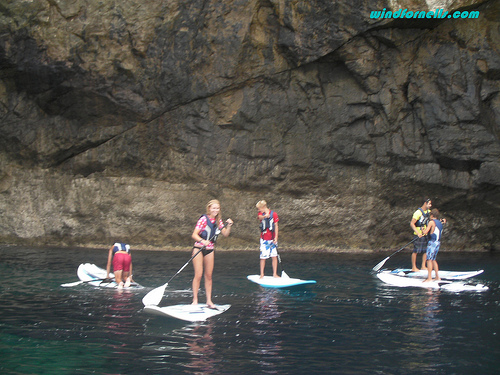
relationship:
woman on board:
[190, 198, 235, 303] [142, 304, 234, 322]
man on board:
[409, 197, 447, 273] [392, 267, 483, 280]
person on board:
[105, 237, 135, 289] [77, 260, 144, 293]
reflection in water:
[254, 286, 280, 325] [0, 246, 497, 371]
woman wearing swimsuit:
[190, 198, 235, 303] [191, 216, 220, 256]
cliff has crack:
[2, 2, 496, 257] [9, 9, 478, 170]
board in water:
[77, 260, 144, 293] [0, 246, 497, 371]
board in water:
[248, 272, 315, 289] [0, 246, 497, 371]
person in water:
[105, 237, 135, 289] [0, 246, 497, 371]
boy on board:
[256, 198, 280, 279] [248, 272, 315, 289]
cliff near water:
[2, 2, 496, 257] [0, 246, 497, 371]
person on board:
[417, 204, 446, 274] [392, 267, 483, 280]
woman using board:
[190, 198, 235, 303] [142, 304, 234, 322]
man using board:
[409, 197, 447, 273] [392, 267, 483, 280]